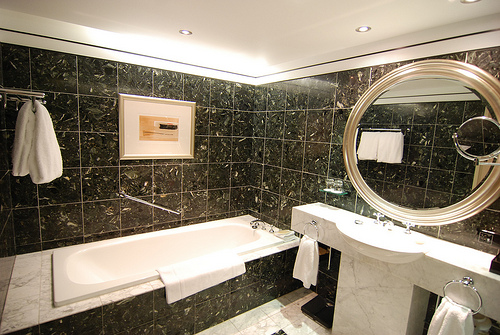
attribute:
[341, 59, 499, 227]
mirror — round, big, large, oval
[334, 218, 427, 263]
sink — white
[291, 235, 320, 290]
towel — white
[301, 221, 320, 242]
ring — silver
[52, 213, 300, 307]
bathtub — white, large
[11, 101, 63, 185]
towel — white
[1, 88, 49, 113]
pole — silver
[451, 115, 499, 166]
mirror — tiny, small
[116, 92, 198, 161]
frame — silver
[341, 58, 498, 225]
frame — silver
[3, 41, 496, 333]
tile — marble, large, dark, black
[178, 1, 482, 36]
light — recessed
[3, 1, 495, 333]
bathroom — large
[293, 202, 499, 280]
counter-top — marble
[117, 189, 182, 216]
rail — slanted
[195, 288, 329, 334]
tile — white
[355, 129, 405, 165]
towels — white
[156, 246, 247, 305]
towel — white